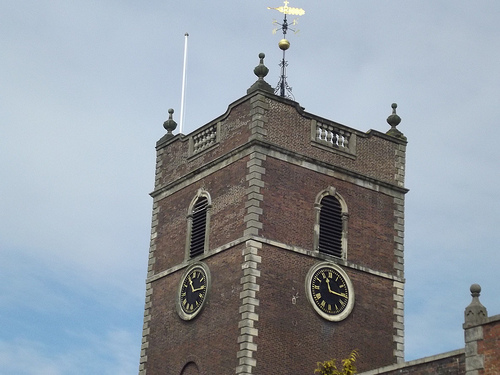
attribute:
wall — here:
[259, 286, 304, 335]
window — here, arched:
[301, 185, 362, 239]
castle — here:
[98, 42, 423, 225]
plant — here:
[312, 333, 382, 374]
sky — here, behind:
[37, 243, 121, 361]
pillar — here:
[455, 302, 496, 362]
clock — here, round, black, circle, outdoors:
[302, 260, 361, 325]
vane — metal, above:
[266, 13, 353, 112]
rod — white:
[149, 29, 235, 123]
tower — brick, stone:
[188, 121, 380, 312]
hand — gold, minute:
[175, 256, 207, 308]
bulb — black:
[161, 23, 212, 54]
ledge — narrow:
[194, 111, 247, 148]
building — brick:
[134, 112, 396, 368]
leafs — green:
[309, 351, 360, 374]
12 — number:
[181, 265, 198, 283]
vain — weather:
[235, 16, 327, 99]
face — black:
[182, 260, 233, 331]